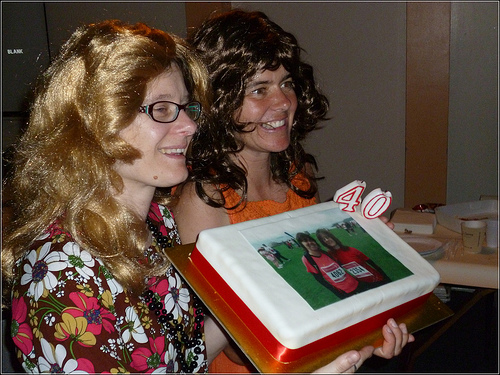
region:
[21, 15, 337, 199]
two women wearing wigs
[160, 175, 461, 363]
birthday cake with portrait in icing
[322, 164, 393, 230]
number shaped birthday candles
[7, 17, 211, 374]
woman in flowered dress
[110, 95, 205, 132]
black eyeglass frames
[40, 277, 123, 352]
pink and yellow flowers on a brown background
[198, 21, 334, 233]
woman in orange sleeveless top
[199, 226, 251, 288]
white frosting on birthday cake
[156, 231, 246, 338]
cardboard cake platter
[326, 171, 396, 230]
candles spelling out the number forty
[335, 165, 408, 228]
candles are a 4 and 0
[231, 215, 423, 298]
picture on the cake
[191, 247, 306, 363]
red ribbon around the cake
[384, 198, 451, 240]
white napkins on the table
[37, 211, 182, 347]
woman's shirt has flowers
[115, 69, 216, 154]
the woman is wearing glasses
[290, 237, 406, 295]
the girls are wearing red shirts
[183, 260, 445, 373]
the women are holding the cake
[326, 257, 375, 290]
there are numbers on their shirts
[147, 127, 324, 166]
the women are smiling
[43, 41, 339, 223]
two women in the photo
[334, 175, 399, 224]
number 40 on cake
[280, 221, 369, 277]
picture of women on cake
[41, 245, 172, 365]
flower dress on woman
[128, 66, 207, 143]
glasses on woman's face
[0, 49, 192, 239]
red hair on woman's head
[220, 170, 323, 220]
orange top on woman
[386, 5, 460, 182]
brown part of wall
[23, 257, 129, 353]
orange, white and yellow flowers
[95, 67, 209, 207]
woman smiling at something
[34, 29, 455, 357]
picture taken indoors.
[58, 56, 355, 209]
Two women holding a cake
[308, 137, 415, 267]
the 40 candles on the cake.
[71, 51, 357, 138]
the women are wearing wigs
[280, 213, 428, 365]
Two women on the cake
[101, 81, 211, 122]
the woman is wearing glasses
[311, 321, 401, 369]
the hands are holding the cake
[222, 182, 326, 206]
the woman's shirt is orange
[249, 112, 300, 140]
the woman is smiling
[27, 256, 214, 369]
the woman is wearing a floral dress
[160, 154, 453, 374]
A cake with two women on it.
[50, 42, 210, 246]
A woman wearing glasses.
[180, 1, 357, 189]
A woman in a wig.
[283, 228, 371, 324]
A frosting painting of two girls.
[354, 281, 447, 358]
A hand holding up a cake.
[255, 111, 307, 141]
the mouth of a young lady.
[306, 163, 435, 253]
The number 40 in candles.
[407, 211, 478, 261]
items on top of a table.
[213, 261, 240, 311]
frosting on a cake.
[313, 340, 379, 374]
A second hand holding a cake.